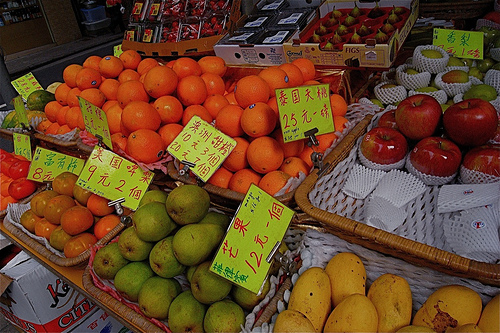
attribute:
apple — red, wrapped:
[358, 123, 410, 170]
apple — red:
[392, 91, 446, 145]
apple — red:
[375, 106, 404, 134]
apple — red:
[440, 95, 499, 151]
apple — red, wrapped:
[406, 134, 465, 181]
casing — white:
[358, 140, 408, 173]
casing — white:
[403, 148, 460, 190]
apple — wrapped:
[461, 140, 499, 183]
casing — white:
[457, 161, 500, 190]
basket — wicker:
[289, 102, 500, 287]